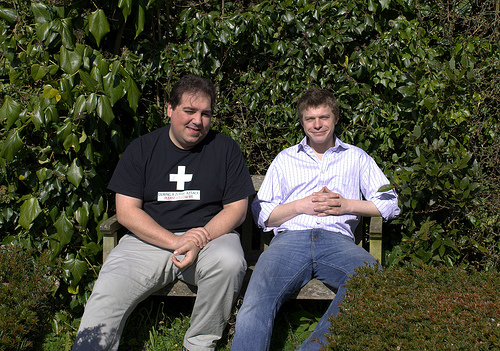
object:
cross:
[164, 162, 197, 192]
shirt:
[109, 127, 256, 232]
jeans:
[68, 232, 249, 351]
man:
[69, 74, 259, 351]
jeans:
[229, 231, 384, 351]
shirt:
[257, 137, 402, 235]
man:
[225, 78, 401, 351]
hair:
[168, 75, 216, 109]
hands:
[169, 239, 202, 272]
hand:
[171, 226, 213, 251]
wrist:
[168, 234, 181, 250]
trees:
[255, 0, 406, 174]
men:
[82, 61, 416, 349]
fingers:
[319, 201, 341, 206]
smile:
[185, 125, 206, 135]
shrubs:
[425, 147, 489, 177]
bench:
[102, 176, 384, 301]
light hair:
[298, 89, 341, 123]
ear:
[165, 101, 173, 117]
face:
[171, 97, 212, 143]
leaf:
[88, 10, 109, 49]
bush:
[247, 19, 338, 66]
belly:
[143, 202, 222, 230]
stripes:
[340, 170, 355, 189]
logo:
[156, 163, 207, 206]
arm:
[99, 213, 117, 242]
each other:
[73, 72, 408, 351]